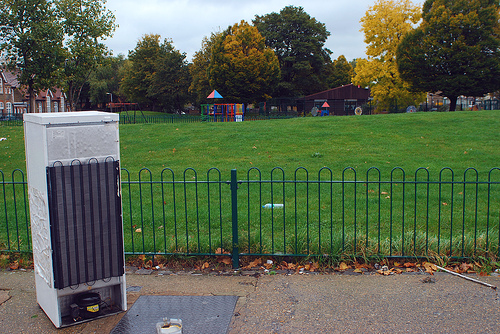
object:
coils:
[46, 154, 124, 289]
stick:
[422, 260, 497, 289]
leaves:
[348, 0, 429, 114]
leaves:
[394, 0, 499, 114]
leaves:
[209, 20, 278, 105]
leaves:
[111, 30, 193, 115]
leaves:
[323, 53, 353, 90]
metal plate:
[109, 294, 240, 334]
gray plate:
[106, 295, 242, 334]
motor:
[68, 292, 100, 321]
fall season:
[188, 20, 281, 101]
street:
[1, 264, 498, 331]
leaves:
[144, 240, 474, 290]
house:
[303, 82, 373, 116]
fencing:
[1, 167, 500, 273]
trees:
[1, 0, 499, 115]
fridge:
[23, 110, 127, 330]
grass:
[0, 108, 499, 254]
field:
[1, 112, 498, 255]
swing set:
[111, 103, 148, 124]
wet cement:
[256, 282, 379, 322]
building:
[0, 62, 72, 120]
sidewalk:
[1, 260, 499, 332]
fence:
[0, 163, 499, 263]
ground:
[0, 255, 497, 334]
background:
[2, 17, 497, 118]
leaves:
[360, 57, 390, 83]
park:
[0, 0, 499, 334]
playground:
[192, 78, 416, 122]